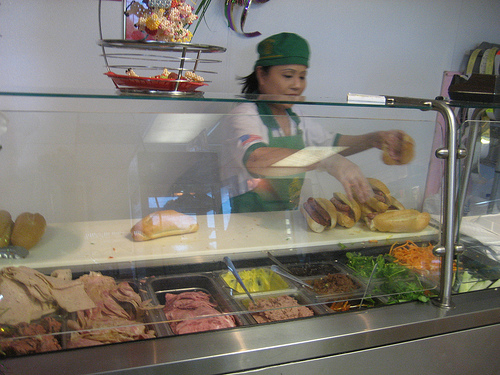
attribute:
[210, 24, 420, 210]
woman — working, female, asian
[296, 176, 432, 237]
sandwiches — white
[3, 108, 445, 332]
plastic — glass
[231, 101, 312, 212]
apron — green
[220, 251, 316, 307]
spoons — silver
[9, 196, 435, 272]
counter top — glass, white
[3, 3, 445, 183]
walls — white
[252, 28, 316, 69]
hat — green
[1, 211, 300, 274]
counter — industrial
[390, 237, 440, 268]
carrots — shredded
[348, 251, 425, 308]
vegetables — green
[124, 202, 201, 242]
bread — light-colored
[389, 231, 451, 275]
food — shredded